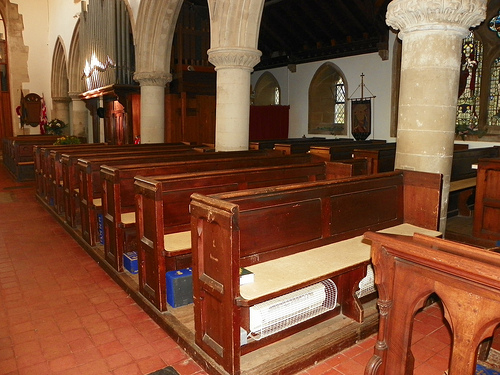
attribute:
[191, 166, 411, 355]
pew — wooden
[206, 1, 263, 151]
column — yellow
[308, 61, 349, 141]
window — black,  brown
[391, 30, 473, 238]
column — white, stone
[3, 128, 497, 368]
bench — wooden, brown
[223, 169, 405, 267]
panels — brown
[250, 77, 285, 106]
arch — brown, white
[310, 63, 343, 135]
arch — brown, white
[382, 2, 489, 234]
column — stone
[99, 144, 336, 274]
bench — brown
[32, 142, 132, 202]
bench — brown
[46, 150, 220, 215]
bench — brown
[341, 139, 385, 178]
bench — brown, wooden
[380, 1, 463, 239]
column — decorative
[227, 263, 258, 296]
book — green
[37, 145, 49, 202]
bench side — brown, wooden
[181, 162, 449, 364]
bench — brown, wooden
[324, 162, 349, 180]
bench side — wooden, brown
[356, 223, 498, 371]
decoration — brown, wooden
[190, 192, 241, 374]
side — brown, bench's, wooden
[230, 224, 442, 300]
cushion — plush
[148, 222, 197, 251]
cushion — plush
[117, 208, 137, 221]
cushion — plush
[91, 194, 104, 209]
cushion — plush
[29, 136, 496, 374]
seats — brown, white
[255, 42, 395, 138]
wall — white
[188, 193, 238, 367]
side — wooden, bench's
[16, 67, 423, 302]
place — of worship